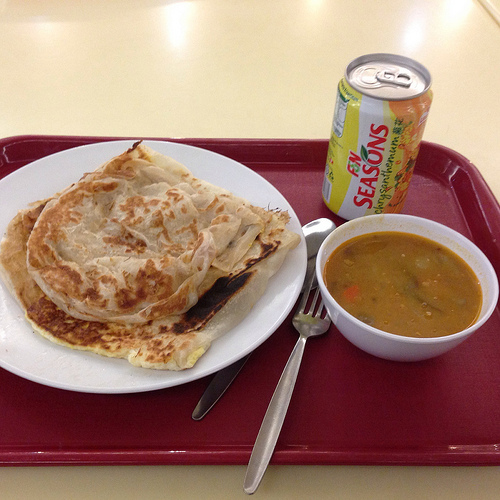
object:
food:
[0, 51, 485, 373]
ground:
[416, 185, 443, 209]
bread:
[0, 142, 303, 371]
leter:
[352, 123, 390, 211]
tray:
[0, 134, 497, 469]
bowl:
[314, 212, 500, 363]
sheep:
[144, 43, 322, 95]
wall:
[0, 3, 497, 138]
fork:
[190, 215, 338, 421]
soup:
[322, 231, 482, 338]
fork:
[240, 270, 333, 497]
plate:
[0, 138, 308, 395]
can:
[320, 52, 435, 221]